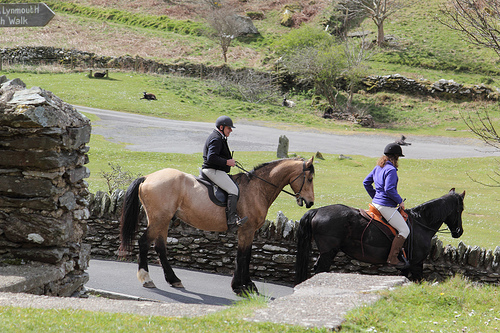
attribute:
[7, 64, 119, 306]
stone wall — tall, dark grey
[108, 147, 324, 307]
horse — brown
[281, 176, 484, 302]
horse — dark brown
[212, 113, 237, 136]
helmet — black 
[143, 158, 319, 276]
horse — brown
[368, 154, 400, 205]
shirt — puple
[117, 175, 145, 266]
hair — black, fluffy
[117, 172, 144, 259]
tail — horse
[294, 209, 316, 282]
tail — black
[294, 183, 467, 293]
horse — black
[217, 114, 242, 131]
helmet — black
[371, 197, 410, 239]
pants — white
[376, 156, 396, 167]
hair — brown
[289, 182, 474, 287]
horse — black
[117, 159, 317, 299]
horse — light brown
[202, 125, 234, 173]
jacket — black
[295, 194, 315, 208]
mouth — open